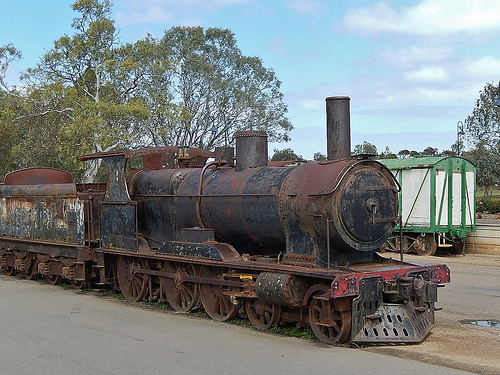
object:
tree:
[54, 65, 134, 130]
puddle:
[464, 310, 499, 330]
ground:
[452, 307, 497, 375]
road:
[33, 317, 207, 375]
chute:
[227, 126, 270, 172]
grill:
[311, 260, 442, 343]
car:
[5, 160, 99, 285]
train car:
[376, 153, 489, 240]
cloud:
[421, 99, 451, 102]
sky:
[377, 65, 406, 87]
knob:
[367, 199, 382, 214]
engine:
[105, 148, 441, 347]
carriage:
[363, 152, 479, 255]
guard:
[332, 260, 442, 347]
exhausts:
[323, 98, 356, 159]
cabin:
[90, 147, 151, 260]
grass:
[76, 297, 377, 347]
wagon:
[0, 169, 105, 284]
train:
[0, 97, 441, 344]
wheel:
[241, 276, 287, 331]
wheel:
[160, 264, 197, 314]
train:
[204, 171, 449, 271]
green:
[410, 159, 472, 186]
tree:
[0, 11, 285, 174]